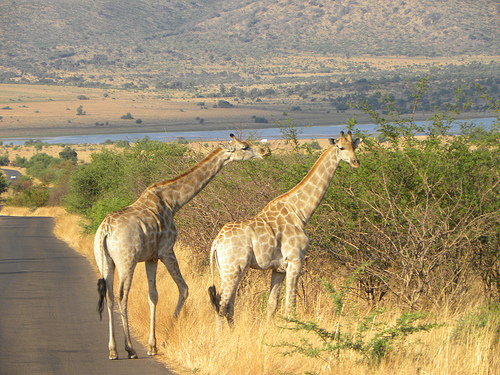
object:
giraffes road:
[0, 200, 181, 374]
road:
[2, 211, 174, 373]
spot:
[182, 185, 191, 194]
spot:
[195, 167, 202, 177]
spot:
[296, 189, 309, 202]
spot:
[308, 174, 320, 186]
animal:
[91, 133, 272, 360]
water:
[0, 112, 486, 144]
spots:
[255, 207, 300, 239]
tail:
[95, 232, 110, 323]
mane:
[133, 146, 224, 180]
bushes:
[2, 141, 493, 371]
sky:
[220, 84, 259, 140]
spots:
[140, 198, 166, 226]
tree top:
[251, 151, 309, 187]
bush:
[75, 105, 86, 115]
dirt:
[2, 46, 487, 120]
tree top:
[153, 146, 185, 157]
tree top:
[368, 95, 485, 165]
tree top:
[276, 113, 299, 135]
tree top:
[55, 151, 87, 156]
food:
[350, 116, 499, 247]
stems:
[328, 173, 483, 303]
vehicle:
[8, 169, 19, 183]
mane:
[249, 134, 334, 210]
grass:
[435, 341, 471, 373]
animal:
[207, 131, 359, 336]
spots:
[285, 193, 302, 210]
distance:
[1, 0, 466, 79]